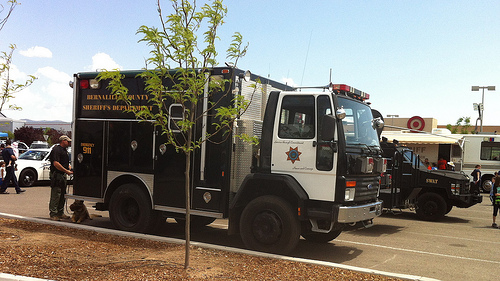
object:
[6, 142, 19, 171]
child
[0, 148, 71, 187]
police car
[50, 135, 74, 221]
man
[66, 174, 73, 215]
leash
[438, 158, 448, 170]
man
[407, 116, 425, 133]
bull eyes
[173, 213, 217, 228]
tire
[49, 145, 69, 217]
fatigues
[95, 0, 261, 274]
tree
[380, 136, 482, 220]
truck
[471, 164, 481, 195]
police presence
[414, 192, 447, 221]
tire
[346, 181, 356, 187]
lights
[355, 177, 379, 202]
grill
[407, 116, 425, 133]
logo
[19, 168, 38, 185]
tire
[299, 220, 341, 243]
wheel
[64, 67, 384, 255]
truck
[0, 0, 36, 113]
tree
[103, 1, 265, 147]
green leaves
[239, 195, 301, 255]
tire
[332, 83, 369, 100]
lights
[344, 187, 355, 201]
headlight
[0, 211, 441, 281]
flower bed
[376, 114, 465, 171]
building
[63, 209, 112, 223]
shade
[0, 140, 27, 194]
man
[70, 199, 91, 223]
dog